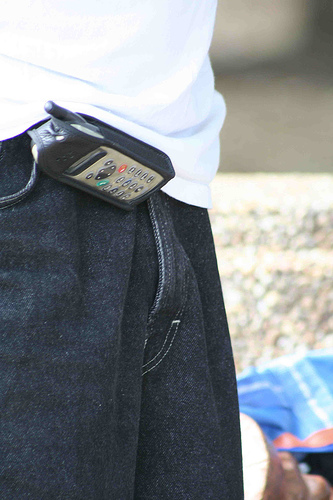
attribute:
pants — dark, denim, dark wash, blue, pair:
[5, 126, 248, 499]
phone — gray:
[26, 98, 181, 216]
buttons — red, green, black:
[124, 166, 156, 183]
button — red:
[116, 162, 130, 174]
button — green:
[94, 180, 110, 190]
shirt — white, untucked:
[0, 1, 223, 212]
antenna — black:
[37, 97, 86, 122]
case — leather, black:
[26, 118, 181, 208]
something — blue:
[224, 347, 332, 466]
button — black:
[115, 174, 125, 184]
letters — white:
[120, 178, 123, 179]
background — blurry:
[215, 0, 331, 374]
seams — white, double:
[151, 314, 177, 382]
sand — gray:
[204, 171, 332, 340]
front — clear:
[65, 151, 159, 205]